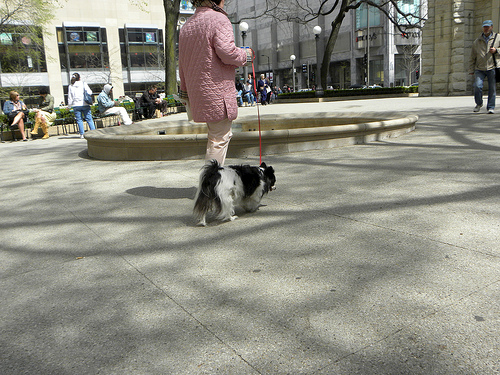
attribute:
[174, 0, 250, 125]
coat — heavy, pink, winter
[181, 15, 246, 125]
jacket — pink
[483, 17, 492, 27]
hat — baseball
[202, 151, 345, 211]
dog — black, white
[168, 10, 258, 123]
jacket — pink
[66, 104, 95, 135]
jeans — blue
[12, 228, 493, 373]
sidewalk — salt, peppered, textured, concrete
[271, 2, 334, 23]
branches — bare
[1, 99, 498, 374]
walkway — concrete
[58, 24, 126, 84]
window — grilled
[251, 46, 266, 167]
leash — red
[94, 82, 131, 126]
person — sitting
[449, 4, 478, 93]
column — rough, white, stone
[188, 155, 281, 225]
dog — small, long haired, black, white, walking